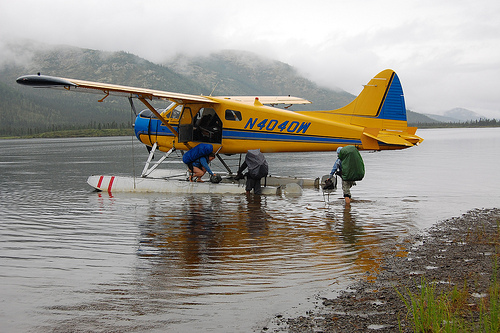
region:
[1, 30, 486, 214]
mountains behind a plane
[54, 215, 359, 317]
reflection on the water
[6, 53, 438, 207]
a yellow plane in the water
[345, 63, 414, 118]
a vertical stabilizer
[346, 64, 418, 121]
a yellow and blue vertical stabilizer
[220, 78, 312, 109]
right wing of plane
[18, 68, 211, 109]
left wing of plane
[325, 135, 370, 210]
man has a green backpack on back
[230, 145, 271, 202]
man has a gray backpack on back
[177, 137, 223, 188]
man has a blue backpack on back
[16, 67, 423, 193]
A yellow, blue and white plane.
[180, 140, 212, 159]
A very large blue pack on a back.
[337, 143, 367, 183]
A very long green pack on a back.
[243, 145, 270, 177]
A very large grey pack on a back.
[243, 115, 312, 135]
N4040W in blue on the side of a plane.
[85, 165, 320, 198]
The white and red bottom of the plane that floats it on water.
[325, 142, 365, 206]
A person in a blue shirt with a green pack on their back.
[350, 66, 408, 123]
A yellow and blue tail end of a plane.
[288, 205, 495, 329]
A grey gravel section of land on this side of the water.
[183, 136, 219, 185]
A person bent over on the side of a plane with a huge blue pack on.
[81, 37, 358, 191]
yellow airplane in water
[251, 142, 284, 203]
man standing in water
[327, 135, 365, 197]
man standing in water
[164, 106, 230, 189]
man standing on plane pontoon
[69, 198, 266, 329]
light reflecting off water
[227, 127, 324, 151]
blue stripe on plane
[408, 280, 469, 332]
grass growing on shore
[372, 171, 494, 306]
mud on edge of water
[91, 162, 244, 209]
white pontoon with red stripes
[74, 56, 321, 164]
mountains in the distance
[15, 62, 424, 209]
an orange water plane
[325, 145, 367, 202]
a man with a large green ruck sack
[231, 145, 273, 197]
a man with a navy blue ruck sack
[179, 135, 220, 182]
a woman with a dark blue ruck sack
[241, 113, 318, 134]
blue text on a plane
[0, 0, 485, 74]
low rolling fog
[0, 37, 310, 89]
distant mountains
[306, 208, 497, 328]
a gravely shore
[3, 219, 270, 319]
ripples on a lake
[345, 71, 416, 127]
the tail of a water plane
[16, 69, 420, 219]
people boarding on n water plane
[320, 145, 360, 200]
a guy carrying luggage in his back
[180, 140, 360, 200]
people carrying their luggage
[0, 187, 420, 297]
ripples in the water body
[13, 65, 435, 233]
a water plane standing in the river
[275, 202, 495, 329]
dirt with some grasses near the river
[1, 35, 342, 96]
fog appearing near the hills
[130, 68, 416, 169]
edge of nose and tail of the plane are painted in blue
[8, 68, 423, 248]
floating plane making ripples in water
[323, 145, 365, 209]
a person holding shoes in left hand